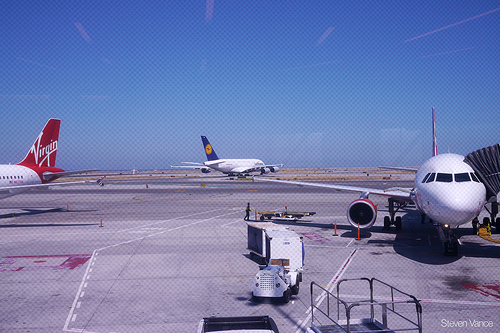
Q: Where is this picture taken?
A: An airport.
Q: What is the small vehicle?
A: Luggage transport.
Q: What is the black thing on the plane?
A: Entry cover.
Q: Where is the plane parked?
A: On the tarmac.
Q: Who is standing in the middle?
A: Maintenance person.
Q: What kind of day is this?
A: Cloudless, sunny day.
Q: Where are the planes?
A: On the tarmac.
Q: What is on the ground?
A: A truck.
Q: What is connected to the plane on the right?
A: A plastic corridor.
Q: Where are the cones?
A: Around the planes.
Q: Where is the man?
A: Walking on the tarmac.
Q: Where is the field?
A: Behind the plane.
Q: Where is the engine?
A: On the wing.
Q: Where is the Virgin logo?
A: On the tail.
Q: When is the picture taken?
A: Daytime.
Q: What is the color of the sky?
A: Blue.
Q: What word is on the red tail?
A: Virgin.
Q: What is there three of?
A: Planes.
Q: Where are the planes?
A: Parked.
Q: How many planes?
A: Three.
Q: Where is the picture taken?
A: On a airport runway.